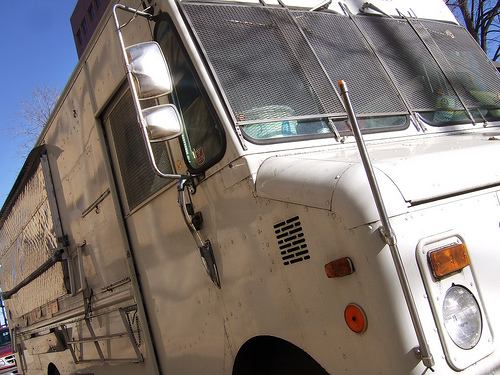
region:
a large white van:
[8, 4, 495, 369]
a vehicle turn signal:
[318, 256, 354, 283]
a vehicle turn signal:
[427, 238, 471, 282]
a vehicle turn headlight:
[438, 282, 482, 354]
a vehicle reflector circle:
[338, 299, 371, 337]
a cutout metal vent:
[269, 215, 313, 270]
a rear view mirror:
[130, 101, 187, 146]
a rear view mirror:
[118, 39, 172, 99]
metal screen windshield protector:
[168, 0, 497, 131]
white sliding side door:
[82, 75, 243, 372]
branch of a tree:
[484, 17, 485, 28]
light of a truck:
[451, 312, 466, 332]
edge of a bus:
[223, 254, 235, 268]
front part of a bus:
[363, 240, 379, 281]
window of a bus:
[421, 85, 457, 90]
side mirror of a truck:
[153, 49, 155, 113]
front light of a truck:
[463, 312, 475, 322]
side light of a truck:
[351, 297, 371, 328]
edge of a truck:
[61, 237, 78, 277]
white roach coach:
[40, 34, 380, 357]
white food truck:
[11, 30, 421, 357]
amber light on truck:
[323, 255, 358, 284]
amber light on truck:
[427, 250, 471, 275]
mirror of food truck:
[118, 40, 183, 149]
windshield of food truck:
[211, 12, 481, 119]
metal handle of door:
[165, 185, 215, 272]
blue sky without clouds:
[5, 12, 46, 109]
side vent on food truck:
[270, 215, 311, 271]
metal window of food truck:
[2, 199, 67, 310]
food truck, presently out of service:
[1, 0, 496, 373]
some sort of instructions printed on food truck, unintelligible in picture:
[266, 211, 316, 273]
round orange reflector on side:
[338, 301, 374, 341]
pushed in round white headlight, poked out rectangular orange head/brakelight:
[420, 240, 485, 355]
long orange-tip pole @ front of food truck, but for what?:
[329, 75, 446, 374]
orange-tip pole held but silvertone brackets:
[372, 221, 443, 373]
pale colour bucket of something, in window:
[234, 98, 303, 148]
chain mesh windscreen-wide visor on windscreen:
[172, 0, 499, 122]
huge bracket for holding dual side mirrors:
[97, 3, 224, 305]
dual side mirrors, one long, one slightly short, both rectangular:
[118, 33, 191, 147]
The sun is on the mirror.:
[110, 8, 207, 183]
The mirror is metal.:
[104, 17, 206, 170]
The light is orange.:
[418, 226, 473, 280]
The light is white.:
[438, 287, 490, 358]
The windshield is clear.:
[182, 4, 498, 138]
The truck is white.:
[10, 12, 489, 372]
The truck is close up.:
[7, 16, 479, 369]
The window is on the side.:
[83, 37, 243, 225]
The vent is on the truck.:
[260, 202, 338, 272]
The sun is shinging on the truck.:
[10, 12, 437, 367]